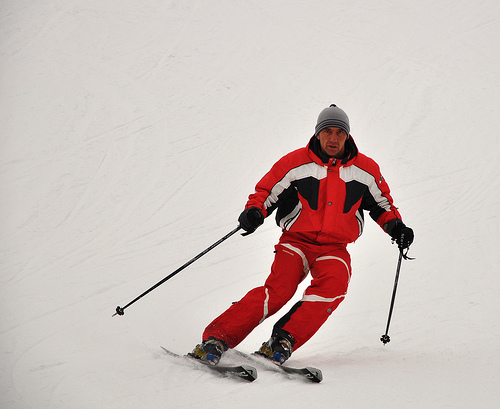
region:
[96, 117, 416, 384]
man skiing down a mountain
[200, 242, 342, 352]
red and white pants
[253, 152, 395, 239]
red, white, and black jacket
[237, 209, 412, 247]
black gloves skier is wearing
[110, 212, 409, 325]
black ski poles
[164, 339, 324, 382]
skis slicing through the snow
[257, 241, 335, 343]
stripes on the pants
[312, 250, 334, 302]
the stripes are white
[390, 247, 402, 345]
the pole is black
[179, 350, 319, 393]
the skis are black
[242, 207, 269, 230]
the glove is black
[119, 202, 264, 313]
pole in the hand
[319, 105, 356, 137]
the beanie is gray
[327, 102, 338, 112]
pom on the beanie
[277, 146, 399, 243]
the jacket is orange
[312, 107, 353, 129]
The gray hat the skier is wearing.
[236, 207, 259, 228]
The glove on the skier's left hand.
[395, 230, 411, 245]
The glove on the skier's right hand.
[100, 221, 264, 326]
The ski pole in the skier's left hand.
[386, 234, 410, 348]
The ski pole in the skier's right hand.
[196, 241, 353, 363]
The red pants the skier is wearing.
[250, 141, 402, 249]
The jacket the skier is wearing.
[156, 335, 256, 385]
The left ski the skier is wearing.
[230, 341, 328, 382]
The right ski the skier is wearing.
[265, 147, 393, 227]
The stripes on the skier's jacket.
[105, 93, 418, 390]
snow skier leaning left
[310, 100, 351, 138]
gray beanie on skier's head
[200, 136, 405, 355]
red and white snow suit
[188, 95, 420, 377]
adult white male skier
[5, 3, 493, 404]
snow covered ski slope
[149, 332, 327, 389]
pair of snow skis on skier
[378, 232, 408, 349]
ski pole in left hand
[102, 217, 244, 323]
ski pole in right hand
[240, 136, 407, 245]
red and white winter jacket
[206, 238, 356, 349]
man wearing red ski pants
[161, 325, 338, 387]
man on black skies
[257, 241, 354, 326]
white stripes on red ski pants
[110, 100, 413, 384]
a man skiing downhill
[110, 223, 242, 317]
a black ski pole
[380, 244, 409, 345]
a black ski pole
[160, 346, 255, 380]
a black and silver ski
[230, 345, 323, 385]
a black and silver ski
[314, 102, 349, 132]
a grey fabric cap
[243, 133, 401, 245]
a red black and white winter coat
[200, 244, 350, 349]
red black and white snow pants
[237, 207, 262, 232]
a black snow glove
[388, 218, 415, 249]
a black snow glove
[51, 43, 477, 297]
this is on a mountain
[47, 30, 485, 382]
this is a ski slope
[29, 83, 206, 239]
the slope is white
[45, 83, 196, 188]
the snow is deep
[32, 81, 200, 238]
the snow is bright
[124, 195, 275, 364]
the ski poles are black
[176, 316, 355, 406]
the skis are black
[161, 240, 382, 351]
the pants are red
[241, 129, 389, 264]
the jacket is red black and white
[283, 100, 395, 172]
head of the man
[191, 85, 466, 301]
man looking at camera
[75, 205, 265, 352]
pole in man's hand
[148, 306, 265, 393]
ski on the snow